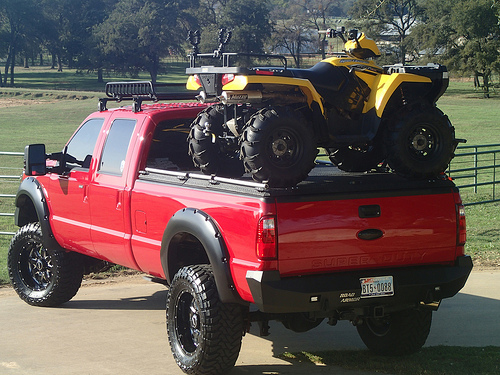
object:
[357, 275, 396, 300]
plate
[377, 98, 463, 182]
tire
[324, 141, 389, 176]
tire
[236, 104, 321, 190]
tire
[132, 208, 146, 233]
cover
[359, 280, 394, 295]
black writing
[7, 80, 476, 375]
truck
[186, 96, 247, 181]
tire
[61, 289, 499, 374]
shadows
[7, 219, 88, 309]
wheel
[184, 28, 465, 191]
vehicle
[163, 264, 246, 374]
wheel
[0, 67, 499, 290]
grass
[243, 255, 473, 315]
bumper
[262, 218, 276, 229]
light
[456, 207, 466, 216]
light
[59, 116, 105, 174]
windows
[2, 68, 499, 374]
ground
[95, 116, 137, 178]
window